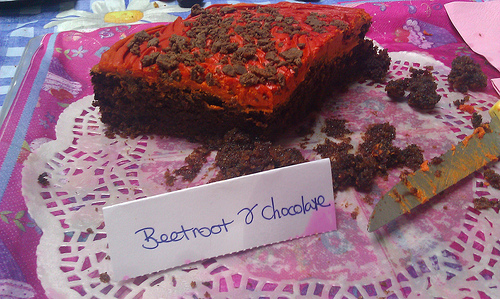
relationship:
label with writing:
[100, 154, 338, 283] [134, 192, 333, 250]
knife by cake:
[361, 105, 499, 241] [89, 0, 371, 139]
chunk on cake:
[279, 45, 302, 60] [89, 2, 488, 189]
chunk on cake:
[141, 50, 159, 67] [89, 2, 488, 189]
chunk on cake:
[157, 52, 178, 72] [89, 2, 488, 189]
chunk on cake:
[145, 36, 157, 47] [89, 2, 488, 189]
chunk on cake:
[257, 36, 271, 45] [89, 2, 488, 189]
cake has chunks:
[89, 0, 371, 139] [329, 51, 482, 194]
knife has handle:
[361, 131, 482, 241] [488, 97, 498, 122]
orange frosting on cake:
[96, 1, 373, 116] [89, 0, 371, 139]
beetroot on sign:
[136, 213, 233, 248] [89, 156, 341, 283]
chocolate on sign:
[260, 188, 332, 224] [89, 156, 341, 283]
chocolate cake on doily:
[83, 1, 382, 151] [21, 35, 498, 297]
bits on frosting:
[155, 33, 294, 69] [99, 2, 373, 107]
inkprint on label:
[137, 210, 244, 247] [100, 157, 367, 283]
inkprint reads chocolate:
[256, 197, 342, 223] [260, 186, 332, 228]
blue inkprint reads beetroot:
[133, 196, 330, 261] [130, 215, 233, 251]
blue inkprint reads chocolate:
[133, 196, 330, 261] [260, 192, 331, 220]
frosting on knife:
[99, 2, 373, 107] [361, 105, 499, 241]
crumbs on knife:
[165, 44, 484, 194] [361, 105, 499, 241]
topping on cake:
[122, 36, 228, 81] [94, 45, 383, 149]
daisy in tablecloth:
[43, 0, 193, 34] [8, 0, 178, 290]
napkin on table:
[443, 1, 498, 71] [0, 0, 500, 297]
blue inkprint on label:
[133, 194, 330, 261] [100, 154, 338, 283]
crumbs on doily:
[199, 122, 422, 188] [21, 35, 498, 297]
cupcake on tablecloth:
[445, 55, 492, 92] [372, 14, 483, 72]